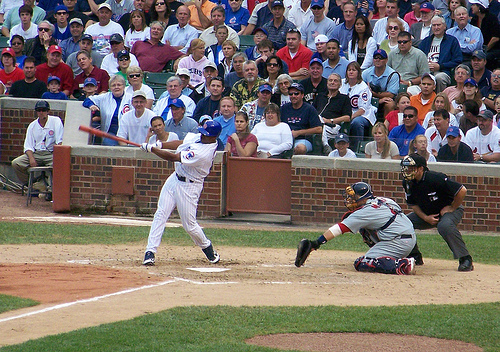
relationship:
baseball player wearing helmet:
[79, 121, 222, 266] [197, 118, 221, 137]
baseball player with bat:
[79, 121, 222, 266] [76, 122, 136, 147]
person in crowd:
[408, 70, 438, 119] [3, 2, 498, 178]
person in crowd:
[345, 15, 374, 65] [3, 2, 498, 178]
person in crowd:
[161, 4, 196, 52] [3, 2, 498, 178]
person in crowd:
[447, 6, 484, 53] [3, 2, 498, 178]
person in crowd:
[128, 20, 179, 69] [3, 2, 498, 178]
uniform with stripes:
[148, 131, 245, 258] [179, 185, 193, 211]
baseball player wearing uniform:
[79, 121, 222, 266] [145, 131, 213, 255]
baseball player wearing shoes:
[137, 118, 226, 273] [126, 245, 230, 275]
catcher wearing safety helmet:
[294, 182, 417, 276] [343, 180, 373, 205]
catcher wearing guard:
[304, 177, 421, 277] [350, 252, 412, 274]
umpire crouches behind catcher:
[387, 147, 488, 279] [297, 177, 419, 270]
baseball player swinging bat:
[79, 121, 222, 266] [75, 124, 140, 150]